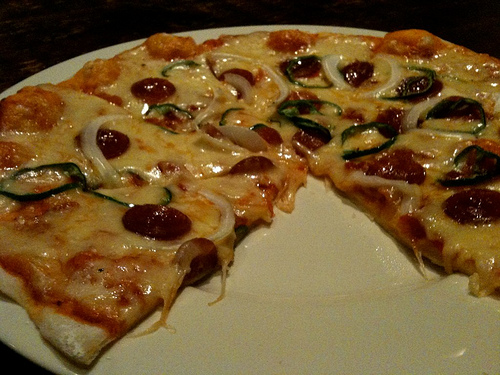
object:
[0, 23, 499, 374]
dinner plate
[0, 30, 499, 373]
cheese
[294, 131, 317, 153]
pepperoni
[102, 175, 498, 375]
space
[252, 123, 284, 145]
pepperoni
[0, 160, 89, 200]
string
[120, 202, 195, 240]
topping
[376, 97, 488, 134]
toppings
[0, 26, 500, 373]
pizza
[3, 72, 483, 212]
green peppers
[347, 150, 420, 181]
pepperoni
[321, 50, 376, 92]
sliver onion